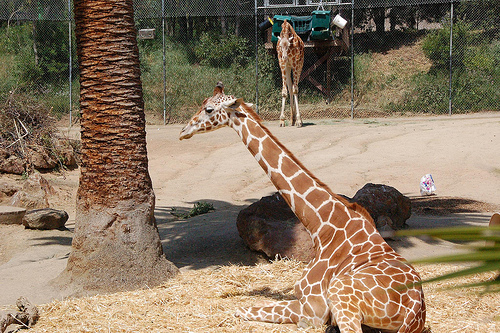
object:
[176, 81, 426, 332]
giraffe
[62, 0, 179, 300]
tree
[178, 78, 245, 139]
head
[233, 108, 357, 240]
neck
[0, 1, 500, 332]
zoo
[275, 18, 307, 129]
giraffe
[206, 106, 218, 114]
eye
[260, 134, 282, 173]
spot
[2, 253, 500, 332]
hay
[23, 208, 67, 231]
rock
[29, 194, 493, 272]
shadow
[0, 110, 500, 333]
ground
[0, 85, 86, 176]
pile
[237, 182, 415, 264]
rocks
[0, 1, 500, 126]
fence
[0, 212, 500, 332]
grass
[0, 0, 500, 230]
background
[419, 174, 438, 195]
bag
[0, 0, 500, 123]
trees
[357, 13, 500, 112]
leaves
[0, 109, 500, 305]
dirt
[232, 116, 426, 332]
spots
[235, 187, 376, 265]
rock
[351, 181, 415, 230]
rock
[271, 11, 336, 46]
feeder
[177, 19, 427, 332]
animals